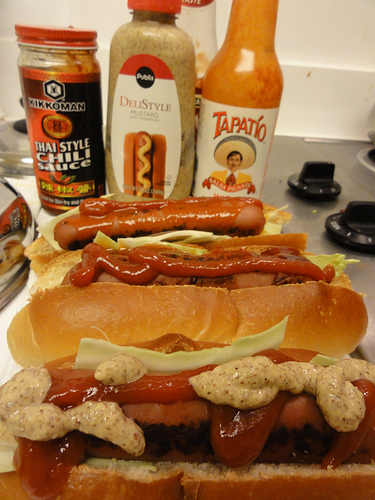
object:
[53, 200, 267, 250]
dogs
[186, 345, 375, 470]
toppings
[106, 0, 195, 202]
bottle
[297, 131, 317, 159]
ground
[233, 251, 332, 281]
ketchup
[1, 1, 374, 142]
wall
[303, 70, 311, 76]
speck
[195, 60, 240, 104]
wall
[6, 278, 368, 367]
bun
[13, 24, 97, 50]
lid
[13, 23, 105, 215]
chili sauce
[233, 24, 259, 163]
sauce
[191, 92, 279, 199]
label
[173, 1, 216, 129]
bottle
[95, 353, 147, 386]
cheese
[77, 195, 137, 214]
ketchup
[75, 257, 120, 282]
ketchup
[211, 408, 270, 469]
ketchup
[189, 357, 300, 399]
mustard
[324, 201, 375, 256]
dials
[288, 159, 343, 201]
dial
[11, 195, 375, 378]
appliance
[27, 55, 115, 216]
ketchup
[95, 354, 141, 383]
mustard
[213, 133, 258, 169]
sombrero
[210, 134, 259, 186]
man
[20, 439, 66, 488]
ketchup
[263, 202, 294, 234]
bun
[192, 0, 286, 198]
hot sauce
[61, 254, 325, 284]
dogs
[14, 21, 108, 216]
bottle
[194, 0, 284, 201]
bottle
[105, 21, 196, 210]
mustard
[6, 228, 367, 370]
hot dog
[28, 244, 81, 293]
bun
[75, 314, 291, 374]
cabbage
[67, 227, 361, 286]
toppings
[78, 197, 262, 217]
toppings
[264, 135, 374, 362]
oven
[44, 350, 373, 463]
hot dog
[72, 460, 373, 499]
bun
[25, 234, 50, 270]
bun